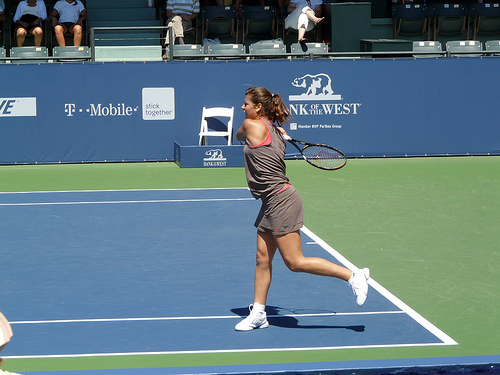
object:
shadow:
[228, 305, 364, 332]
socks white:
[251, 302, 265, 315]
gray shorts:
[254, 184, 304, 235]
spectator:
[283, 2, 325, 43]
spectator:
[163, 0, 202, 45]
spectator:
[50, 0, 86, 47]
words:
[65, 104, 132, 117]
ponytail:
[272, 93, 290, 124]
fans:
[13, 1, 47, 47]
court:
[0, 153, 499, 375]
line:
[8, 310, 405, 323]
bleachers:
[167, 45, 203, 60]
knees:
[256, 251, 263, 261]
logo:
[142, 87, 175, 120]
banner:
[0, 57, 498, 162]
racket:
[282, 134, 347, 171]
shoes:
[234, 312, 269, 331]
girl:
[236, 87, 370, 330]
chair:
[199, 106, 234, 145]